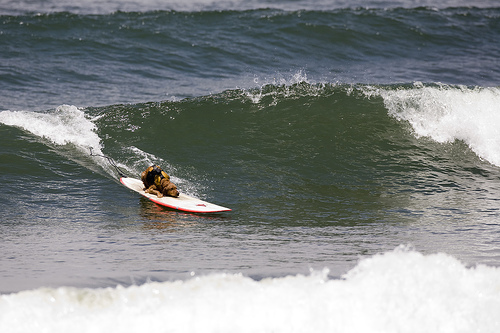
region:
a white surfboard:
[95, 179, 261, 224]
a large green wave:
[4, 79, 497, 189]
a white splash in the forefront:
[6, 247, 498, 331]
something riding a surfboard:
[98, 156, 245, 224]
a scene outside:
[12, 14, 497, 307]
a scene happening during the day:
[5, 12, 461, 324]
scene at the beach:
[5, 10, 472, 325]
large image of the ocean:
[4, 2, 486, 297]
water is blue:
[2, 6, 494, 297]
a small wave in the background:
[4, 2, 499, 57]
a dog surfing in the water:
[62, 47, 272, 295]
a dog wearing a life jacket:
[107, 104, 286, 281]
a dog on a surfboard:
[54, 140, 245, 257]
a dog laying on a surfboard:
[99, 111, 310, 302]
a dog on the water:
[91, 120, 285, 268]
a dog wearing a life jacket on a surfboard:
[54, 110, 293, 278]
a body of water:
[224, 70, 496, 313]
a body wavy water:
[224, 50, 476, 330]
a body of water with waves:
[219, 37, 477, 332]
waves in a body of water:
[241, 61, 485, 309]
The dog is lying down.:
[97, 160, 237, 224]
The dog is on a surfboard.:
[105, 157, 225, 221]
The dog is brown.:
[103, 137, 241, 244]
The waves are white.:
[2, 5, 499, 322]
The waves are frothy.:
[1, 72, 498, 329]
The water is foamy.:
[1, 75, 499, 330]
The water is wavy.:
[3, 5, 497, 330]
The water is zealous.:
[3, 4, 498, 329]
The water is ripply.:
[1, 0, 498, 331]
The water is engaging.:
[0, 2, 499, 327]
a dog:
[84, 121, 279, 291]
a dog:
[42, 42, 224, 279]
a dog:
[122, 74, 402, 325]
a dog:
[123, 31, 245, 267]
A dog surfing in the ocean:
[0, 0, 497, 330]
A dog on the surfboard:
[112, 158, 234, 223]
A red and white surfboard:
[117, 176, 230, 220]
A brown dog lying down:
[138, 163, 179, 206]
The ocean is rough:
[9, 8, 477, 182]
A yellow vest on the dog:
[139, 158, 174, 187]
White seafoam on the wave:
[0, 96, 115, 163]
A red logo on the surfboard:
[190, 199, 211, 207]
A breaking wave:
[193, 83, 484, 175]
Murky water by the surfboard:
[224, 108, 416, 212]